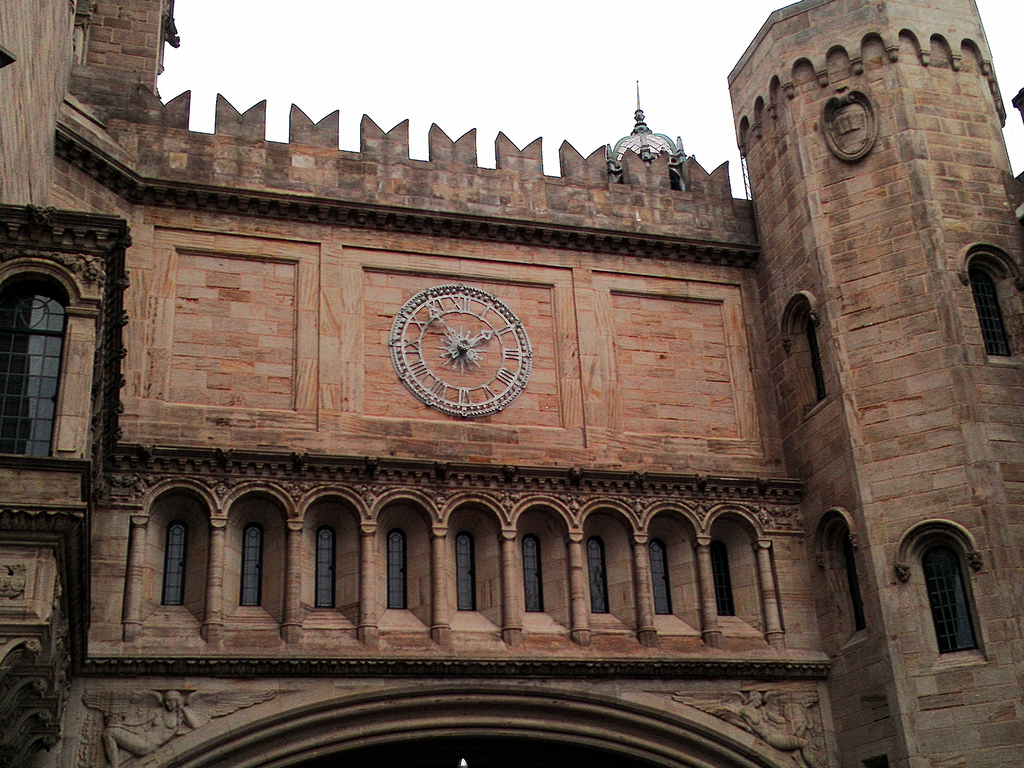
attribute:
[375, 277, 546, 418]
clock — round  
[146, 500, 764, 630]
windows — rowed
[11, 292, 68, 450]
window — black inset 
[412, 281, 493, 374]
angel — stone relief 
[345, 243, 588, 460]
design — square, brick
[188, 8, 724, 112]
sky — cloudy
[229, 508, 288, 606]
window — glass 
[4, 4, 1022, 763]
building — castle , large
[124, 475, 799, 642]
windows — arched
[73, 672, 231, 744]
carvings — decorative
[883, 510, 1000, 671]
window — arched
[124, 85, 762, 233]
brick — ridged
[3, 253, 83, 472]
window — black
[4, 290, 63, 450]
dividers — glass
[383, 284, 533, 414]
clock — large, decorative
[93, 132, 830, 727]
wall — stone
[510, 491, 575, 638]
window — arched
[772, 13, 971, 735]
wall — stone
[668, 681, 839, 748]
angel — carved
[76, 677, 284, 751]
angel — carved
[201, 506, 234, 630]
pillars — decorative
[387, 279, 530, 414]
face — clock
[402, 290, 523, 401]
numerals — roman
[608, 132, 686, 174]
roof — domed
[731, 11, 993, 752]
tower — brown stone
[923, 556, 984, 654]
pane — window